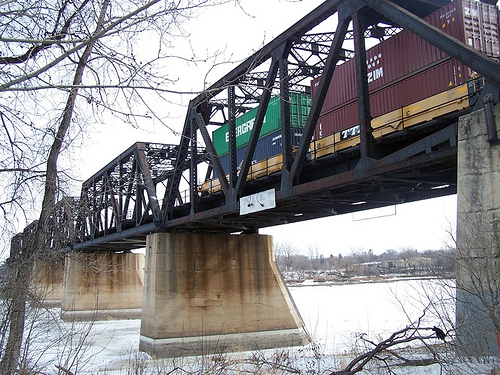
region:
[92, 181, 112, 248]
steel beam on bridge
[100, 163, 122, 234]
steel beam on bridge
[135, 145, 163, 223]
steel beam on bridge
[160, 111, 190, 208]
steel beam on bridge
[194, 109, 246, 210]
steel beam on bridge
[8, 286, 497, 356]
a fast flowing river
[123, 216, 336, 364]
a concrete support foundation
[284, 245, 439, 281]
a quaint town by the river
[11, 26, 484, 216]
a train bridge with a train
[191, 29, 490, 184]
two train cars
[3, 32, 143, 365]
a tree mourns for the summer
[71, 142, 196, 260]
a section of bridge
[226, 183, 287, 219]
a sign on the bridge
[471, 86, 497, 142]
a drain pipe on the bridge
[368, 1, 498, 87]
metal beam on bridge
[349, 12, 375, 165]
metal beam on bridge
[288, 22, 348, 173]
metal beam on bridge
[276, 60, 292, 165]
metal beam on bridge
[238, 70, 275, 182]
metal beam on bridge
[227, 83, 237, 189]
metal beam on bridge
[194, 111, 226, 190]
metal beam on bridge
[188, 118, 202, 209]
metal beam on bridge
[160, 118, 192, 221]
metal beam on bridge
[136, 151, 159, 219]
metal beam on bridge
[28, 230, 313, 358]
the beige columns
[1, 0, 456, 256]
the bridge overhead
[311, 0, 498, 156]
the dark red units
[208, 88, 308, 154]
the green unit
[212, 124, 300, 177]
the navy blue unit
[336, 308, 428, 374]
the branches on the ground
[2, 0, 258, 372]
the trees to the left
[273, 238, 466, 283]
the view of the city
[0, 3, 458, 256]
the clear sky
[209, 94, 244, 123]
empty branch of tree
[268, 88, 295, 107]
empty branch of tree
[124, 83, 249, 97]
empty branch of tree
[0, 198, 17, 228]
empty branch of tree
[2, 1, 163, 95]
empty branch of tree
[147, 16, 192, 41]
empty branch of tree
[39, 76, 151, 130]
empty branch of tree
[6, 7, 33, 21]
empty branch of tree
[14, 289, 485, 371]
a river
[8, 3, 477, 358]
a train bridge over a river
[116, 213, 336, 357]
a bridge foundation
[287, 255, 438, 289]
a town by the river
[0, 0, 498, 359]
large bridge over a river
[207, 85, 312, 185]
green and blue train car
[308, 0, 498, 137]
metal dark brown train car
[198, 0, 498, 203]
train crossing a metal bridge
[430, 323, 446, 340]
black object stuck in the branches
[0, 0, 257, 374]
bare trees next to a bridge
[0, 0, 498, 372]
the trees are bare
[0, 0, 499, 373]
the branches are thin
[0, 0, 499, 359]
the large pillars holding up the bridge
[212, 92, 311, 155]
the crate is green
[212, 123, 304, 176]
the crate is dark blue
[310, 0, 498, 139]
the crates are maroon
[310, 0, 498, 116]
the crate is maroon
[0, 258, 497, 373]
the snow is white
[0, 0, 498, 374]
the bright sky above the snow